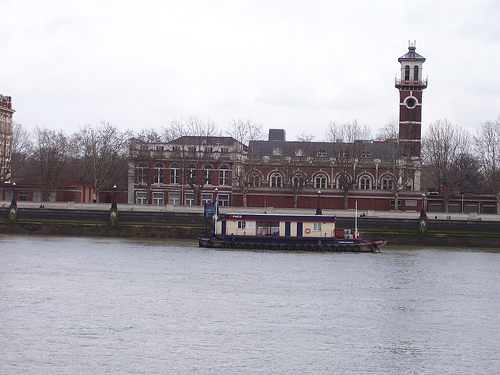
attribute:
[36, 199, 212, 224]
train — blue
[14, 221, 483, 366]
river — ightly rippling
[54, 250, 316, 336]
river — placid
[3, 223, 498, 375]
water — calm, placid, moving, silver, smooth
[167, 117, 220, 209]
tree — bare,  wood,  leafless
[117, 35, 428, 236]
building —  little, red, made, light yellow, tall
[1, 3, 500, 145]
sky — cloudy, gray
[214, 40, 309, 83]
cloud — white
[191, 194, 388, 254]
boat — blue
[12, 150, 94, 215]
building — orange